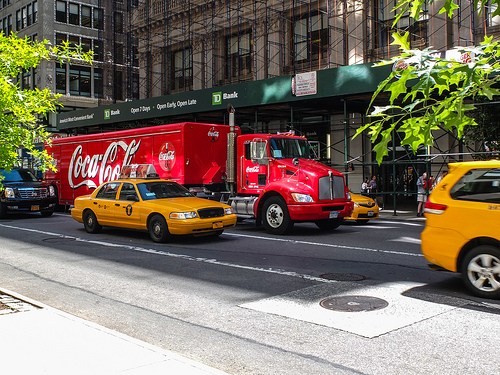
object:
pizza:
[179, 243, 274, 305]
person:
[416, 171, 430, 217]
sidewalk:
[379, 208, 425, 221]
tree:
[0, 29, 100, 197]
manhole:
[319, 272, 367, 281]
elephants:
[65, 162, 247, 249]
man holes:
[317, 294, 389, 313]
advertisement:
[119, 164, 156, 178]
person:
[368, 175, 383, 212]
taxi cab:
[343, 191, 379, 223]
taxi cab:
[70, 164, 238, 243]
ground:
[0, 209, 497, 373]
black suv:
[0, 167, 59, 218]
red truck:
[43, 122, 355, 235]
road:
[0, 237, 439, 375]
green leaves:
[0, 31, 93, 195]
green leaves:
[366, 31, 455, 115]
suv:
[420, 158, 498, 300]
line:
[0, 222, 339, 284]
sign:
[291, 68, 317, 97]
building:
[96, 0, 498, 208]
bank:
[223, 91, 239, 99]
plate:
[212, 222, 223, 229]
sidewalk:
[0, 287, 230, 375]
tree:
[349, 1, 500, 167]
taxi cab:
[420, 159, 499, 298]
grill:
[318, 174, 346, 199]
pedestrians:
[360, 177, 373, 196]